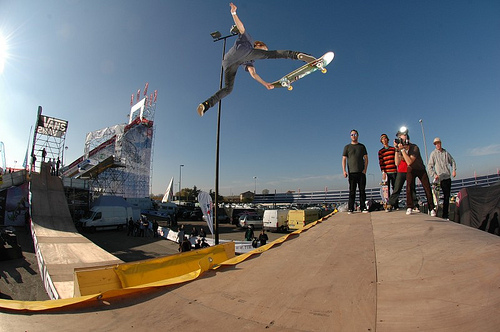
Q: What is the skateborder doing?
A: A trick.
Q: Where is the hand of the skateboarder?
A: Holding the board.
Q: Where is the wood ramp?
A: Under the skateboarder.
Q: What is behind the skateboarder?
A: Lights.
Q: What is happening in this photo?
A: Skateboarding.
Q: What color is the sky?
A: Blue.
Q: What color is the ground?
A: Gray.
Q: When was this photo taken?
A: Outside, during the daytime.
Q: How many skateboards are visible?
A: One.